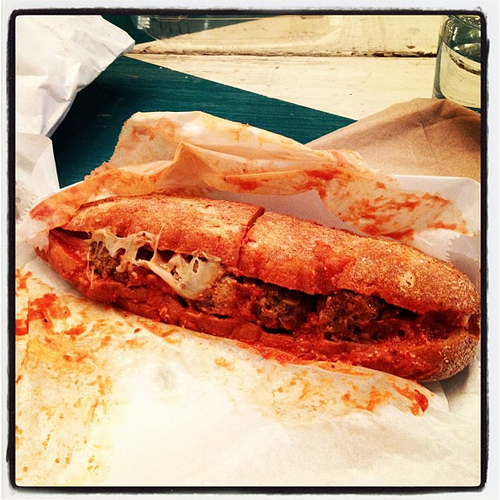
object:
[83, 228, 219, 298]
cheese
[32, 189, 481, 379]
bread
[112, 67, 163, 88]
green surface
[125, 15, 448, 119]
table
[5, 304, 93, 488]
surface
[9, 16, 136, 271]
paper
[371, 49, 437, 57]
stains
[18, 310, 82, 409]
sauce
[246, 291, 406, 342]
meat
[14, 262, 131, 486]
stains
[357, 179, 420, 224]
sauce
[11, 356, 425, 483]
paper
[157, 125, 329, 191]
surface